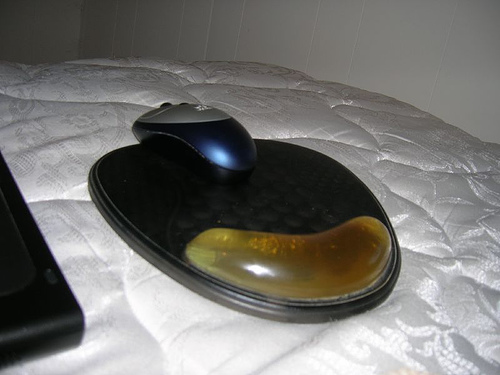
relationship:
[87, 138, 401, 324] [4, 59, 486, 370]
mouse pad on bed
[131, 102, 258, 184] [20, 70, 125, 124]
mouse sitting on bed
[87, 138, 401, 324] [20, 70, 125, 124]
mouse pad sitting on bed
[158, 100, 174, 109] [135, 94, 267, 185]
scroller on top of mouse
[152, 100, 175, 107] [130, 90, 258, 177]
wheel in center of mouse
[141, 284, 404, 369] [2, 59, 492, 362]
light reflected on mattress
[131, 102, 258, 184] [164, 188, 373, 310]
mouse on to of mousepad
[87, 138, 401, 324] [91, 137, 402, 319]
mouse pad on pad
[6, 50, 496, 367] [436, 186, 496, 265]
blanket on flower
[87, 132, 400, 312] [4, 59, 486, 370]
mouse pad on bed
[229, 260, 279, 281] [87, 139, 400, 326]
reflected light on wristrest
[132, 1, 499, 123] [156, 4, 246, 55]
wall with bars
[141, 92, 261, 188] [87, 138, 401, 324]
mouse on mouse pad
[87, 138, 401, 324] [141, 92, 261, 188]
mouse pad with mouse